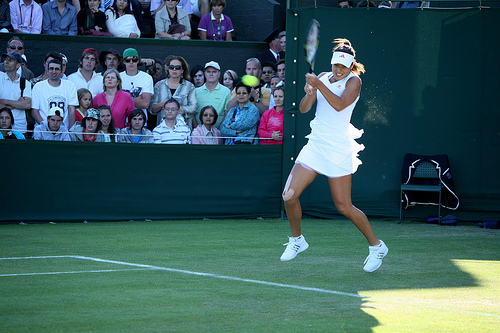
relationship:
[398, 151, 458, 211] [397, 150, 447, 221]
jacket hanging on chair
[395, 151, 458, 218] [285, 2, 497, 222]
blue chair by wall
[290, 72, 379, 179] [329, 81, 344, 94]
dress with symbol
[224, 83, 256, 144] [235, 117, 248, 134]
woman in shirt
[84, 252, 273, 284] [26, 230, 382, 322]
line on court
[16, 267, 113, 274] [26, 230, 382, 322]
line on court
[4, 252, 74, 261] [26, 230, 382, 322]
line on court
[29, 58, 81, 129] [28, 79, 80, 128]
man in shirt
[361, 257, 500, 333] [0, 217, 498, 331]
sunlight reflecting ground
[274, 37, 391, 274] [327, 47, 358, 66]
woman wearing visor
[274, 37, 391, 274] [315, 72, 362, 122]
woman wearing t shirt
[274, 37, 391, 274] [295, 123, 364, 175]
woman wearing skirt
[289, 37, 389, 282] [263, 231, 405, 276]
woman wearing tennis shoes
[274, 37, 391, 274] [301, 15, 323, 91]
woman holding racket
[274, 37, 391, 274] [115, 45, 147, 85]
woman wearing cap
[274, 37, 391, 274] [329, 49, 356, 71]
woman wearing visor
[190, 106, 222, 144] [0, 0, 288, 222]
woman sitting in stands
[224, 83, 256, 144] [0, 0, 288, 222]
woman sitting in stands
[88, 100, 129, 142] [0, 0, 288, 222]
woman sitting in stands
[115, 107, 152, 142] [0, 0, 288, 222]
man on stands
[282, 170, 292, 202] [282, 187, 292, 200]
bandage on knee